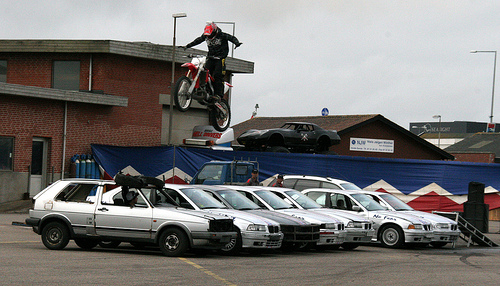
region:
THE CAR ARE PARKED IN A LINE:
[58, 149, 446, 259]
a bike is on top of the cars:
[138, 24, 263, 125]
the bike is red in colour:
[172, 58, 217, 81]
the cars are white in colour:
[325, 170, 430, 252]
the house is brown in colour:
[28, 112, 87, 134]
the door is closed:
[32, 138, 48, 195]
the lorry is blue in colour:
[188, 155, 261, 183]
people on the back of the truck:
[242, 164, 295, 183]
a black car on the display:
[243, 113, 340, 158]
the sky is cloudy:
[311, 26, 424, 86]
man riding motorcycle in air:
[170, 20, 246, 134]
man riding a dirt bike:
[158, 11, 254, 133]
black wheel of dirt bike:
[170, 76, 197, 111]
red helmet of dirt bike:
[200, 22, 222, 34]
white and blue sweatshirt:
[198, 31, 230, 57]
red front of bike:
[178, 58, 203, 72]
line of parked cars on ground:
[55, 179, 336, 244]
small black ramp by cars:
[447, 210, 474, 250]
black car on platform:
[242, 123, 340, 146]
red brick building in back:
[112, 48, 172, 123]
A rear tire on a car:
[40, 218, 69, 250]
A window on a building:
[51, 62, 79, 92]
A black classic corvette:
[238, 120, 340, 149]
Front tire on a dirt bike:
[172, 75, 196, 111]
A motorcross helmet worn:
[200, 20, 220, 40]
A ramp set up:
[431, 210, 498, 247]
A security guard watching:
[245, 169, 265, 184]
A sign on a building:
[347, 136, 394, 153]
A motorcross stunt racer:
[174, 21, 241, 131]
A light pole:
[166, 10, 186, 144]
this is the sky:
[283, 20, 433, 98]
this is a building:
[58, 37, 158, 132]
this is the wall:
[112, 65, 167, 94]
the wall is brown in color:
[113, 59, 163, 95]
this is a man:
[194, 20, 236, 81]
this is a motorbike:
[171, 53, 218, 100]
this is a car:
[54, 169, 195, 251]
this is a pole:
[490, 55, 498, 84]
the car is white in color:
[102, 207, 139, 224]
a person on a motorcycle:
[171, 20, 243, 110]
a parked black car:
[235, 121, 332, 151]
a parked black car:
[193, 182, 319, 249]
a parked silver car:
[163, 178, 281, 249]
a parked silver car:
[27, 168, 240, 256]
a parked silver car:
[230, 185, 348, 246]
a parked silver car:
[301, 187, 432, 246]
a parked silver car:
[366, 190, 460, 246]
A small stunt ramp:
[431, 208, 498, 249]